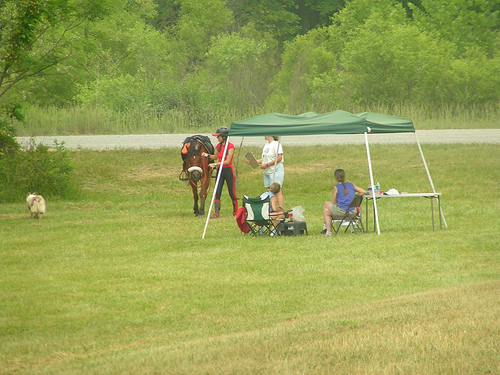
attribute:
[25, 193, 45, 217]
dog — standing, white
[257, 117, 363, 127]
canopy — green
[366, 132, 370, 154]
pole — white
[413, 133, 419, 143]
pole — white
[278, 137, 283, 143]
pole — white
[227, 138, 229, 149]
pole — white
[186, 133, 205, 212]
horse — standing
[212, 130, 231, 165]
female — upright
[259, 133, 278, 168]
female — upright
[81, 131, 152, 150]
road — gravel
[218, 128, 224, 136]
helmet — black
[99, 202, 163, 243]
grass — cut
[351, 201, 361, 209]
chair — dark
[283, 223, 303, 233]
stool — black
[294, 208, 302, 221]
bag — clear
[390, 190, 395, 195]
bag — white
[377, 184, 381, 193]
bottle — clear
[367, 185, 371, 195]
bottle — clear